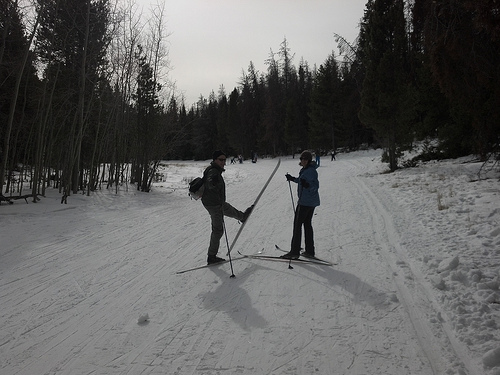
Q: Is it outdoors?
A: Yes, it is outdoors.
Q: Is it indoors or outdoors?
A: It is outdoors.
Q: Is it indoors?
A: No, it is outdoors.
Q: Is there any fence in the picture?
A: No, there are no fences.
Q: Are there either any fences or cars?
A: No, there are no fences or cars.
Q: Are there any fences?
A: No, there are no fences.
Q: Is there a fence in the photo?
A: No, there are no fences.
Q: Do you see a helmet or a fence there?
A: No, there are no fences or helmets.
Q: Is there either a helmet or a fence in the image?
A: No, there are no fences or helmets.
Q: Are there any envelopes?
A: No, there are no envelopes.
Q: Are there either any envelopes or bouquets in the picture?
A: No, there are no envelopes or bouquets.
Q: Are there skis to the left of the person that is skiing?
A: Yes, there is a ski to the left of the person.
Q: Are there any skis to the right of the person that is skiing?
A: No, the ski is to the left of the person.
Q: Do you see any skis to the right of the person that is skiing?
A: No, the ski is to the left of the person.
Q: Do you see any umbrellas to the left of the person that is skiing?
A: No, there is a ski to the left of the person.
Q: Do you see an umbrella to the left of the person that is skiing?
A: No, there is a ski to the left of the person.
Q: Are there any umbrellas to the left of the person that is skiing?
A: No, there is a ski to the left of the person.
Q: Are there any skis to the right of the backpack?
A: Yes, there is a ski to the right of the backpack.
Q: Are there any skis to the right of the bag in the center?
A: Yes, there is a ski to the right of the backpack.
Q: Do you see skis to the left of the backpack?
A: No, the ski is to the right of the backpack.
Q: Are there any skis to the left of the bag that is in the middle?
A: No, the ski is to the right of the backpack.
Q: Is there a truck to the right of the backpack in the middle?
A: No, there is a ski to the right of the backpack.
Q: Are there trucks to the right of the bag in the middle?
A: No, there is a ski to the right of the backpack.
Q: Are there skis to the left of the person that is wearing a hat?
A: Yes, there is a ski to the left of the person.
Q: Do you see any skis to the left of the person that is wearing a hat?
A: Yes, there is a ski to the left of the person.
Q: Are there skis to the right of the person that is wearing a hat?
A: No, the ski is to the left of the person.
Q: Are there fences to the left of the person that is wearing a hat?
A: No, there is a ski to the left of the person.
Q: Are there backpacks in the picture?
A: Yes, there is a backpack.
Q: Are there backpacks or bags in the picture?
A: Yes, there is a backpack.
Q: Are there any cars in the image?
A: No, there are no cars.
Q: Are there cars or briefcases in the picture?
A: No, there are no cars or briefcases.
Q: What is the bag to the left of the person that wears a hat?
A: The bag is a backpack.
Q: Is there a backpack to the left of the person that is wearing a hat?
A: Yes, there is a backpack to the left of the person.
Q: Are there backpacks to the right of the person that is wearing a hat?
A: No, the backpack is to the left of the person.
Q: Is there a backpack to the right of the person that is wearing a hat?
A: No, the backpack is to the left of the person.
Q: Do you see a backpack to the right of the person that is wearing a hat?
A: No, the backpack is to the left of the person.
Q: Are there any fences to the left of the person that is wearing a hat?
A: No, there is a backpack to the left of the person.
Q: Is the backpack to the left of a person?
A: Yes, the backpack is to the left of a person.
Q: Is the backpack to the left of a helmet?
A: No, the backpack is to the left of a person.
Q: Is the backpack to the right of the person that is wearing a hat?
A: No, the backpack is to the left of the person.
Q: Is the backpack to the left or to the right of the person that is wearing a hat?
A: The backpack is to the left of the person.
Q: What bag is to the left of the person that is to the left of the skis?
A: The bag is a backpack.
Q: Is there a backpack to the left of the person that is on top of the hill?
A: Yes, there is a backpack to the left of the person.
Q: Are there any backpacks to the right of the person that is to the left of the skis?
A: No, the backpack is to the left of the person.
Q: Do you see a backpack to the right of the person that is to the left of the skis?
A: No, the backpack is to the left of the person.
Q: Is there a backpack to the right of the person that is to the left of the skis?
A: No, the backpack is to the left of the person.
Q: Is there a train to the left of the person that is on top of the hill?
A: No, there is a backpack to the left of the person.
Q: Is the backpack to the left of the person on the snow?
A: Yes, the backpack is to the left of the person.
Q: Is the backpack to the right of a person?
A: No, the backpack is to the left of a person.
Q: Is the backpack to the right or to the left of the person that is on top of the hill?
A: The backpack is to the left of the person.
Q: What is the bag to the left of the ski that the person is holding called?
A: The bag is a backpack.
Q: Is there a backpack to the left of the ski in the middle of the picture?
A: Yes, there is a backpack to the left of the ski.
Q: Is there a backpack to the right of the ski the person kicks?
A: No, the backpack is to the left of the ski.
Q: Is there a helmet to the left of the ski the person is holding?
A: No, there is a backpack to the left of the ski.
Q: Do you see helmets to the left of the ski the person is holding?
A: No, there is a backpack to the left of the ski.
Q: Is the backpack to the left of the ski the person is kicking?
A: Yes, the backpack is to the left of the ski.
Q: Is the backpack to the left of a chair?
A: No, the backpack is to the left of the ski.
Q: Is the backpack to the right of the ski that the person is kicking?
A: No, the backpack is to the left of the ski.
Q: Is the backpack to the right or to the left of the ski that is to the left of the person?
A: The backpack is to the left of the ski.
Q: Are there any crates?
A: No, there are no crates.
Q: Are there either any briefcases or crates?
A: No, there are no crates or briefcases.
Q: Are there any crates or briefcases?
A: No, there are no crates or briefcases.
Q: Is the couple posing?
A: Yes, the couple is posing.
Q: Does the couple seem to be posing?
A: Yes, the couple is posing.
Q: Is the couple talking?
A: No, the couple is posing.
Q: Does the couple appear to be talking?
A: No, the couple is posing.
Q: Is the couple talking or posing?
A: The couple is posing.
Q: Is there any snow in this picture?
A: Yes, there is snow.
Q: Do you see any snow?
A: Yes, there is snow.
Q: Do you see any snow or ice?
A: Yes, there is snow.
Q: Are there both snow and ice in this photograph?
A: Yes, there are both snow and ice.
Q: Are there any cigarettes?
A: No, there are no cigarettes.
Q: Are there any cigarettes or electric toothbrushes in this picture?
A: No, there are no cigarettes or electric toothbrushes.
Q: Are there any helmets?
A: No, there are no helmets.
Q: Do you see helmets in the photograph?
A: No, there are no helmets.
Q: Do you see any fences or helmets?
A: No, there are no helmets or fences.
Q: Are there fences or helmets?
A: No, there are no helmets or fences.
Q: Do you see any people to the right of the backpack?
A: Yes, there is a person to the right of the backpack.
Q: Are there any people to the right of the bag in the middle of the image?
A: Yes, there is a person to the right of the backpack.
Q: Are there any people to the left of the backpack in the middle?
A: No, the person is to the right of the backpack.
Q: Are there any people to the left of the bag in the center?
A: No, the person is to the right of the backpack.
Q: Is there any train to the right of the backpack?
A: No, there is a person to the right of the backpack.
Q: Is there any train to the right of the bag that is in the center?
A: No, there is a person to the right of the backpack.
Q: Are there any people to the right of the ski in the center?
A: Yes, there is a person to the right of the ski.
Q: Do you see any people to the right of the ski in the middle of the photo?
A: Yes, there is a person to the right of the ski.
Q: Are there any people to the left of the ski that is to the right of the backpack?
A: No, the person is to the right of the ski.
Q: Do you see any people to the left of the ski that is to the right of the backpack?
A: No, the person is to the right of the ski.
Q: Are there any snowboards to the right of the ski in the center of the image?
A: No, there is a person to the right of the ski.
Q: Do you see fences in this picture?
A: No, there are no fences.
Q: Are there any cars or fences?
A: No, there are no fences or cars.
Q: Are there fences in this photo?
A: No, there are no fences.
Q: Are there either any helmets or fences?
A: No, there are no fences or helmets.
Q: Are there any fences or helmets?
A: No, there are no fences or helmets.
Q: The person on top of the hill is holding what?
A: The person is holding the ski.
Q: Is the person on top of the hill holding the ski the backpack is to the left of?
A: Yes, the person is holding the ski.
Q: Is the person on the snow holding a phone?
A: No, the person is holding the ski.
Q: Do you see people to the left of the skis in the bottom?
A: Yes, there is a person to the left of the skis.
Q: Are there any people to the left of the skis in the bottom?
A: Yes, there is a person to the left of the skis.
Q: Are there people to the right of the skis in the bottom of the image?
A: No, the person is to the left of the skis.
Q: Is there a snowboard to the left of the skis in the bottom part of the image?
A: No, there is a person to the left of the skis.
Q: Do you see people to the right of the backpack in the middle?
A: Yes, there is a person to the right of the backpack.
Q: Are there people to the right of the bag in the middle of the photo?
A: Yes, there is a person to the right of the backpack.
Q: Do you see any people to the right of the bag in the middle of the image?
A: Yes, there is a person to the right of the backpack.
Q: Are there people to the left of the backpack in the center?
A: No, the person is to the right of the backpack.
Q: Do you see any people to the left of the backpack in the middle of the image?
A: No, the person is to the right of the backpack.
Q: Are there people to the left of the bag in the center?
A: No, the person is to the right of the backpack.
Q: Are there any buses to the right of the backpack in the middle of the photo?
A: No, there is a person to the right of the backpack.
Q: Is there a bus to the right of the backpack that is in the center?
A: No, there is a person to the right of the backpack.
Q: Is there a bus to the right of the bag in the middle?
A: No, there is a person to the right of the backpack.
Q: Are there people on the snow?
A: Yes, there is a person on the snow.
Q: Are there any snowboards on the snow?
A: No, there is a person on the snow.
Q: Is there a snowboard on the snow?
A: No, there is a person on the snow.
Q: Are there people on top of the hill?
A: Yes, there is a person on top of the hill.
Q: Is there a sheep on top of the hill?
A: No, there is a person on top of the hill.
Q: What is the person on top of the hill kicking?
A: The person is kicking the ski.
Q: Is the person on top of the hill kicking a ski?
A: Yes, the person is kicking a ski.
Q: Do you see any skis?
A: Yes, there are skis.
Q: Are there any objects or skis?
A: Yes, there are skis.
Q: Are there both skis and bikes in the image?
A: No, there are skis but no bikes.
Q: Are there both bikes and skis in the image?
A: No, there are skis but no bikes.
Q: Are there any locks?
A: No, there are no locks.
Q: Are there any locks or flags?
A: No, there are no locks or flags.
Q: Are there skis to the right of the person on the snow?
A: Yes, there are skis to the right of the person.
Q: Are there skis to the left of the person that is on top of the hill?
A: No, the skis are to the right of the person.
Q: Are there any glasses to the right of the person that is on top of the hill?
A: No, there are skis to the right of the person.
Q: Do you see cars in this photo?
A: No, there are no cars.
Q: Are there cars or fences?
A: No, there are no cars or fences.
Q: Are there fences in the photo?
A: No, there are no fences.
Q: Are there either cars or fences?
A: No, there are no fences or cars.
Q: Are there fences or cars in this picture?
A: No, there are no fences or cars.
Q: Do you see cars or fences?
A: No, there are no fences or cars.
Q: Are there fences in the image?
A: No, there are no fences.